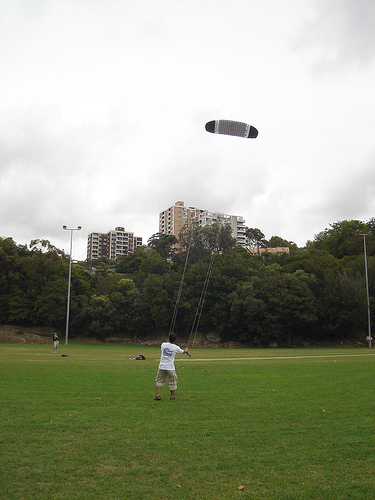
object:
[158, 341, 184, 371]
shirt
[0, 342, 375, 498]
ground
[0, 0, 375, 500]
picture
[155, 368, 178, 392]
shorts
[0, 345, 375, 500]
grass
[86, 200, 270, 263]
buildings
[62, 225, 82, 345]
light pole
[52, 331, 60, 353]
girl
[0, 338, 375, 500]
field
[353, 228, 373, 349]
post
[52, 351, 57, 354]
shoe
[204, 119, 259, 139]
kite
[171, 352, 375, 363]
line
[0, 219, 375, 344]
tree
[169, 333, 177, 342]
dark hair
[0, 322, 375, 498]
park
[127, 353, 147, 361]
people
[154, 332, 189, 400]
guy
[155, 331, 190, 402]
kite flyer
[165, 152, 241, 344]
strings